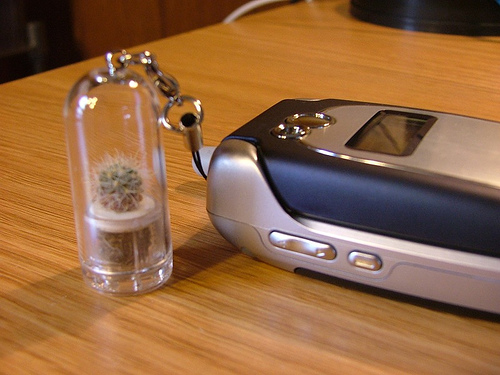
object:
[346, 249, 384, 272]
button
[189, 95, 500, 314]
call phone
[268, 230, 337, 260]
button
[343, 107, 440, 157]
screen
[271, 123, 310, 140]
lens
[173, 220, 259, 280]
shade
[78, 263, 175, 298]
edge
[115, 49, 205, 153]
chain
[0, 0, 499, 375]
table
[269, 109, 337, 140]
camera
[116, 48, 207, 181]
strap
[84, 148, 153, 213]
ball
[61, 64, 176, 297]
container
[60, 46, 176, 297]
glass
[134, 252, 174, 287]
edge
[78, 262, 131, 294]
edge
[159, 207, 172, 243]
edge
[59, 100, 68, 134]
edge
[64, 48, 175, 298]
decoration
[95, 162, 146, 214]
cactus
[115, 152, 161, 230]
glass part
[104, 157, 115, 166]
thorns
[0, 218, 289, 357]
shadow